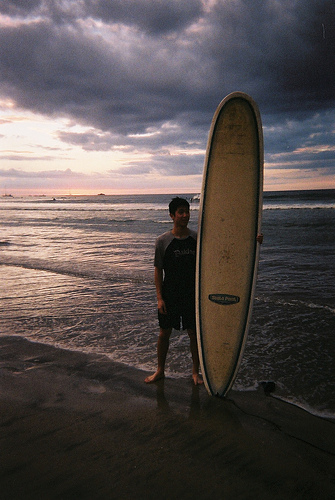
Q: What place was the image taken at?
A: It was taken at the ocean.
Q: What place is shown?
A: It is an ocean.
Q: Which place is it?
A: It is an ocean.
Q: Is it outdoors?
A: Yes, it is outdoors.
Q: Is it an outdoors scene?
A: Yes, it is outdoors.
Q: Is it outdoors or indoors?
A: It is outdoors.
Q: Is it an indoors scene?
A: No, it is outdoors.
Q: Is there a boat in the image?
A: No, there are no boats.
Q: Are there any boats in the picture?
A: No, there are no boats.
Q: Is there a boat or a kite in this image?
A: No, there are no boats or kites.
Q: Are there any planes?
A: No, there are no planes.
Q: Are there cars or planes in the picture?
A: No, there are no planes or cars.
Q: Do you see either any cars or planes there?
A: No, there are no planes or cars.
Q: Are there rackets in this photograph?
A: No, there are no rackets.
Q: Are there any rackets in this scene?
A: No, there are no rackets.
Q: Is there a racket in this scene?
A: No, there are no rackets.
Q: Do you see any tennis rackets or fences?
A: No, there are no tennis rackets or fences.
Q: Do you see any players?
A: No, there are no players.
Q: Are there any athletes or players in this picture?
A: No, there are no players or athletes.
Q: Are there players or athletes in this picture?
A: No, there are no players or athletes.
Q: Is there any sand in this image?
A: Yes, there is sand.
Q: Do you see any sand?
A: Yes, there is sand.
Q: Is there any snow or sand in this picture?
A: Yes, there is sand.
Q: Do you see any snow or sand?
A: Yes, there is sand.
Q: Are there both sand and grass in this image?
A: No, there is sand but no grass.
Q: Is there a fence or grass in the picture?
A: No, there are no fences or grass.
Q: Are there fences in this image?
A: No, there are no fences.